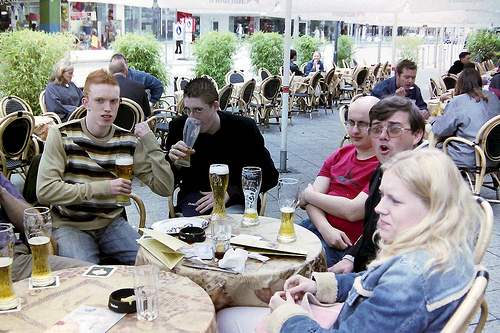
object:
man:
[166, 75, 278, 217]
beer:
[108, 117, 267, 229]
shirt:
[316, 145, 381, 248]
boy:
[34, 66, 176, 269]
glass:
[108, 149, 136, 213]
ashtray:
[168, 207, 211, 252]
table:
[137, 214, 322, 276]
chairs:
[218, 70, 278, 114]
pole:
[271, 17, 292, 174]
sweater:
[43, 126, 175, 229]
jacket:
[274, 241, 478, 331]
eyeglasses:
[179, 102, 206, 117]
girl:
[287, 148, 481, 292]